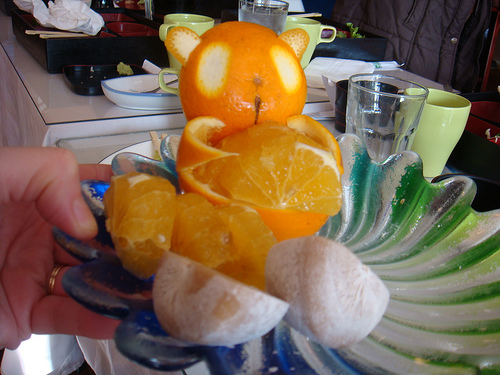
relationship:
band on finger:
[44, 263, 64, 295] [43, 264, 159, 304]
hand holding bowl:
[1, 145, 119, 349] [51, 131, 498, 373]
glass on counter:
[340, 54, 429, 166] [0, 12, 498, 292]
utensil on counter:
[25, 27, 90, 44] [0, 6, 402, 147]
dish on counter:
[85, 76, 180, 119] [0, 6, 402, 147]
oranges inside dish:
[97, 17, 396, 350] [45, 122, 496, 370]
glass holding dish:
[345, 73, 429, 164] [103, 60, 194, 114]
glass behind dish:
[345, 73, 429, 164] [45, 122, 496, 370]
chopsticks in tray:
[26, 27, 91, 42] [13, 13, 169, 75]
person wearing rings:
[2, 145, 175, 357] [45, 260, 64, 287]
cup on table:
[344, 71, 427, 156] [1, 14, 498, 306]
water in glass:
[243, 12, 282, 34] [243, 3, 280, 18]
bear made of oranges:
[151, 1, 366, 240] [89, 10, 426, 372]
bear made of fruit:
[163, 20, 344, 242] [105, 15, 389, 349]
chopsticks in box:
[25, 30, 90, 39] [16, 14, 174, 73]